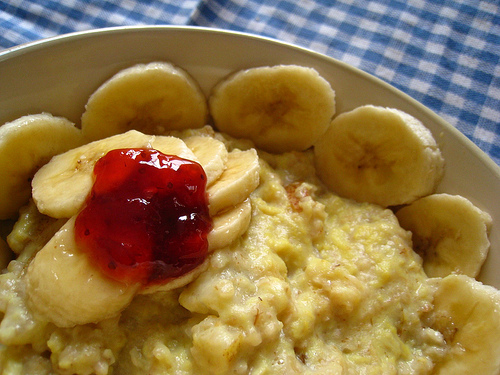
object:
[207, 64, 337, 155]
banana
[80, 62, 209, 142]
banana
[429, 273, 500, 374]
banana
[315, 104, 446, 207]
banana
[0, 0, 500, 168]
crease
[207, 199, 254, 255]
bananas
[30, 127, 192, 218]
bananas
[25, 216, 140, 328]
banana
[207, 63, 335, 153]
banana slice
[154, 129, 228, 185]
bananas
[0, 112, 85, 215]
bananas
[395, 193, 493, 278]
bananas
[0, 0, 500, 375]
table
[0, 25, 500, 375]
bowl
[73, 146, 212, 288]
jam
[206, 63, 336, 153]
circles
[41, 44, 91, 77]
bowl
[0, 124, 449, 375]
chunk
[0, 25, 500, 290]
part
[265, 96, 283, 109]
seed